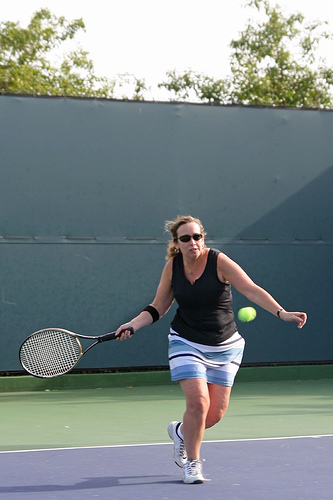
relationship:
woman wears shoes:
[115, 215, 308, 483] [162, 418, 215, 484]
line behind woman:
[0, 433, 331, 455] [115, 215, 308, 483]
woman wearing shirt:
[119, 199, 278, 463] [162, 252, 234, 348]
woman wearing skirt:
[115, 215, 308, 483] [133, 313, 258, 378]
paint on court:
[4, 453, 295, 498] [2, 99, 328, 495]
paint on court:
[0, 437, 332, 499] [3, 382, 331, 497]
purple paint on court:
[227, 445, 309, 486] [100, 465, 213, 496]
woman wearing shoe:
[115, 215, 308, 483] [166, 419, 185, 463]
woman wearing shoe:
[115, 215, 308, 483] [181, 457, 205, 483]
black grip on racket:
[95, 332, 121, 342] [7, 304, 146, 382]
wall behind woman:
[0, 114, 241, 357] [161, 218, 248, 469]